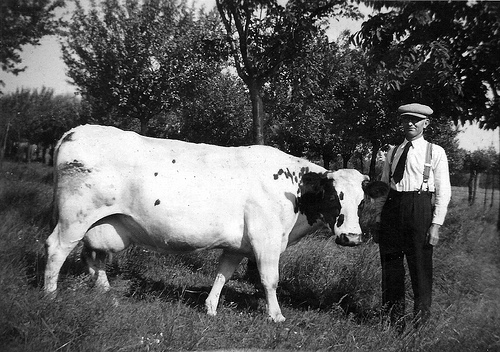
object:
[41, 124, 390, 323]
cow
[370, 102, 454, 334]
man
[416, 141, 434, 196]
suspenders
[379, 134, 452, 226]
shirt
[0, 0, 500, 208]
tree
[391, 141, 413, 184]
tie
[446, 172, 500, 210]
fence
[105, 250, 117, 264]
udders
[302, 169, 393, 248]
head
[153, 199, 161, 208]
spot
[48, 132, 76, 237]
tail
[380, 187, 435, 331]
pants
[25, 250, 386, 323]
shadow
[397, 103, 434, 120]
hat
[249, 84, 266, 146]
trunk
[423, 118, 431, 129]
ear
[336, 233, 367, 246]
nose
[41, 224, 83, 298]
leg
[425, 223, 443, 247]
hand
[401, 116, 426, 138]
face